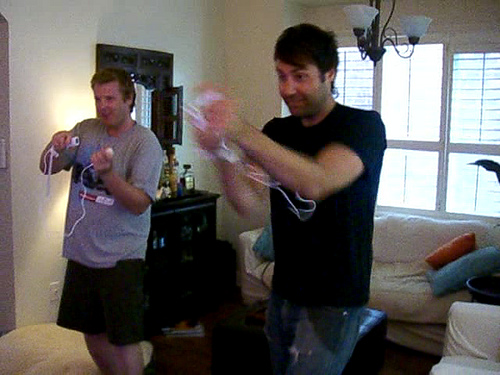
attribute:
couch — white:
[249, 197, 499, 366]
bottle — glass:
[178, 160, 197, 195]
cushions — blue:
[427, 241, 490, 297]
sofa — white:
[237, 207, 497, 356]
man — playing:
[28, 69, 173, 364]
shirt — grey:
[41, 122, 166, 262]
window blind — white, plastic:
[451, 91, 498, 106]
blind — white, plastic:
[446, 120, 498, 132]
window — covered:
[447, 38, 497, 215]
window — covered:
[375, 44, 441, 209]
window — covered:
[287, 50, 372, 112]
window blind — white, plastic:
[430, 87, 487, 138]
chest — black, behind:
[144, 187, 224, 339]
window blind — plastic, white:
[450, 40, 499, 200]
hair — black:
[269, 20, 341, 102]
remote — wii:
[187, 96, 247, 167]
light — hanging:
[342, 3, 434, 58]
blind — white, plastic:
[446, 48, 498, 216]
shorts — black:
[42, 252, 159, 343]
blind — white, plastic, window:
[453, 80, 498, 94]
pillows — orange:
[404, 210, 489, 280]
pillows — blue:
[421, 242, 497, 292]